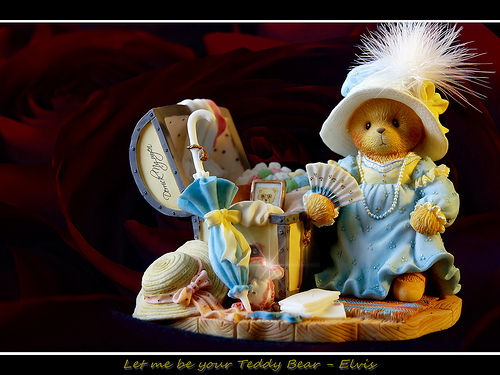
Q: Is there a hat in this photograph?
A: Yes, there is a hat.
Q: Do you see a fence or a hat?
A: Yes, there is a hat.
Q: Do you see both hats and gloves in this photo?
A: No, there is a hat but no gloves.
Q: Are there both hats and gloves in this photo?
A: No, there is a hat but no gloves.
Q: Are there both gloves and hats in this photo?
A: No, there is a hat but no gloves.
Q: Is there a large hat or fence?
A: Yes, there is a large hat.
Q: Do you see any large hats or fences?
A: Yes, there is a large hat.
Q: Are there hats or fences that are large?
A: Yes, the hat is large.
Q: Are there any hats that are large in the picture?
A: Yes, there is a large hat.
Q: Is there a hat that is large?
A: Yes, there is a hat that is large.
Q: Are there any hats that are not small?
A: Yes, there is a large hat.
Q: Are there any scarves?
A: No, there are no scarves.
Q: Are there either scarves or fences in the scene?
A: No, there are no scarves or fences.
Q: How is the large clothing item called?
A: The clothing item is a hat.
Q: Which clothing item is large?
A: The clothing item is a hat.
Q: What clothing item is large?
A: The clothing item is a hat.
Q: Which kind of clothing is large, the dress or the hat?
A: The hat is large.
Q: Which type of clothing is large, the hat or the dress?
A: The hat is large.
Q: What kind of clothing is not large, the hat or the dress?
A: The dress is not large.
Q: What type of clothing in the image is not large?
A: The clothing is a dress.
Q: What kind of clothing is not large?
A: The clothing is a dress.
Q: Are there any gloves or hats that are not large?
A: No, there is a hat but it is large.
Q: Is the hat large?
A: Yes, the hat is large.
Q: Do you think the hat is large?
A: Yes, the hat is large.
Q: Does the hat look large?
A: Yes, the hat is large.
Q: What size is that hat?
A: The hat is large.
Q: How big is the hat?
A: The hat is large.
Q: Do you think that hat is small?
A: No, the hat is large.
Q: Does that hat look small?
A: No, the hat is large.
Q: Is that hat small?
A: No, the hat is large.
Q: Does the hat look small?
A: No, the hat is large.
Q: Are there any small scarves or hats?
A: No, there is a hat but it is large.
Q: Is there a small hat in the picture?
A: No, there is a hat but it is large.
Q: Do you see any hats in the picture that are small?
A: No, there is a hat but it is large.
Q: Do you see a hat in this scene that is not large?
A: No, there is a hat but it is large.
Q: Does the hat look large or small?
A: The hat is large.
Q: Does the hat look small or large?
A: The hat is large.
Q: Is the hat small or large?
A: The hat is large.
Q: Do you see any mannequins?
A: No, there are no mannequins.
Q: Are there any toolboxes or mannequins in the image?
A: No, there are no mannequins or toolboxes.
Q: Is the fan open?
A: Yes, the fan is open.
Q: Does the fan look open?
A: Yes, the fan is open.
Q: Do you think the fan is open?
A: Yes, the fan is open.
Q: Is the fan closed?
A: No, the fan is open.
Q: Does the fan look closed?
A: No, the fan is open.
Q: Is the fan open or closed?
A: The fan is open.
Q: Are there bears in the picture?
A: Yes, there is a bear.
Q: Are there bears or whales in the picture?
A: Yes, there is a bear.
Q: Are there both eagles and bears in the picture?
A: No, there is a bear but no eagles.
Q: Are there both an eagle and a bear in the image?
A: No, there is a bear but no eagles.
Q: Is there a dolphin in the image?
A: No, there are no dolphins.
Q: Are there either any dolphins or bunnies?
A: No, there are no dolphins or bunnies.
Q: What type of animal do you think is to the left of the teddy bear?
A: The animal is a bear.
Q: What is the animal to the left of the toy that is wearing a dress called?
A: The animal is a bear.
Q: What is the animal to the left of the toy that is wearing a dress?
A: The animal is a bear.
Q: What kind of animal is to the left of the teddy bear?
A: The animal is a bear.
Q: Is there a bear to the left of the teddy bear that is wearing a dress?
A: Yes, there is a bear to the left of the teddy bear.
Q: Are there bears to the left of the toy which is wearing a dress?
A: Yes, there is a bear to the left of the teddy bear.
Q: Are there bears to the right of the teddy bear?
A: No, the bear is to the left of the teddy bear.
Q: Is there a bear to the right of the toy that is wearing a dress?
A: No, the bear is to the left of the teddy bear.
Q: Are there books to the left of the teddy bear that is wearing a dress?
A: No, there is a bear to the left of the teddy bear.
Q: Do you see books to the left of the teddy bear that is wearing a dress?
A: No, there is a bear to the left of the teddy bear.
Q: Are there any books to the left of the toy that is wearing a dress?
A: No, there is a bear to the left of the teddy bear.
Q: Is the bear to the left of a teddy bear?
A: Yes, the bear is to the left of a teddy bear.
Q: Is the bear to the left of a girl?
A: No, the bear is to the left of a teddy bear.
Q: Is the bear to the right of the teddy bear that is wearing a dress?
A: No, the bear is to the left of the teddy bear.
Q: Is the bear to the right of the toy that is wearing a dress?
A: No, the bear is to the left of the teddy bear.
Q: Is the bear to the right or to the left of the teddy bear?
A: The bear is to the left of the teddy bear.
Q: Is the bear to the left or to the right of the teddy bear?
A: The bear is to the left of the teddy bear.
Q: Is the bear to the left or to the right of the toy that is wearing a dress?
A: The bear is to the left of the teddy bear.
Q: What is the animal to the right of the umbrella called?
A: The animal is a bear.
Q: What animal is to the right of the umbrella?
A: The animal is a bear.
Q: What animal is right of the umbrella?
A: The animal is a bear.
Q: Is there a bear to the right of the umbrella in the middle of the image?
A: Yes, there is a bear to the right of the umbrella.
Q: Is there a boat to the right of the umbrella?
A: No, there is a bear to the right of the umbrella.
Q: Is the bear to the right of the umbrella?
A: Yes, the bear is to the right of the umbrella.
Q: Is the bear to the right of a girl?
A: No, the bear is to the right of the umbrella.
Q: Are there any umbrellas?
A: Yes, there is an umbrella.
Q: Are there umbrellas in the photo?
A: Yes, there is an umbrella.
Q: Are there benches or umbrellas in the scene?
A: Yes, there is an umbrella.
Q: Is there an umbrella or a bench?
A: Yes, there is an umbrella.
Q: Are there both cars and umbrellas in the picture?
A: No, there is an umbrella but no cars.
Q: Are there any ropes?
A: No, there are no ropes.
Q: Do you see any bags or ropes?
A: No, there are no ropes or bags.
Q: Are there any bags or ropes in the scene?
A: No, there are no ropes or bags.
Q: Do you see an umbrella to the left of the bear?
A: Yes, there is an umbrella to the left of the bear.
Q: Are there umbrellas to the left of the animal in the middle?
A: Yes, there is an umbrella to the left of the bear.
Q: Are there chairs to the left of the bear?
A: No, there is an umbrella to the left of the bear.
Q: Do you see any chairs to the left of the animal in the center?
A: No, there is an umbrella to the left of the bear.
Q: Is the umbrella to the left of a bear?
A: Yes, the umbrella is to the left of a bear.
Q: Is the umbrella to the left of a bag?
A: No, the umbrella is to the left of a bear.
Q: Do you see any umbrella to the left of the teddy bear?
A: Yes, there is an umbrella to the left of the teddy bear.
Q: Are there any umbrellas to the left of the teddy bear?
A: Yes, there is an umbrella to the left of the teddy bear.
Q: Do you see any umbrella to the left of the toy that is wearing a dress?
A: Yes, there is an umbrella to the left of the teddy bear.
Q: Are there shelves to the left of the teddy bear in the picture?
A: No, there is an umbrella to the left of the teddy bear.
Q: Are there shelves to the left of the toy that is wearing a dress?
A: No, there is an umbrella to the left of the teddy bear.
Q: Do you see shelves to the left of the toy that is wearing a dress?
A: No, there is an umbrella to the left of the teddy bear.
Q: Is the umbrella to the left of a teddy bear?
A: Yes, the umbrella is to the left of a teddy bear.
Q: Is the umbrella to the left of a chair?
A: No, the umbrella is to the left of a teddy bear.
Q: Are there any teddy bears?
A: Yes, there is a teddy bear.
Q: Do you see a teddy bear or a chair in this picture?
A: Yes, there is a teddy bear.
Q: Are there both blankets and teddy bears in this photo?
A: No, there is a teddy bear but no blankets.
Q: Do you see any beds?
A: No, there are no beds.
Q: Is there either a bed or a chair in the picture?
A: No, there are no beds or chairs.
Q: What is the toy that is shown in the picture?
A: The toy is a teddy bear.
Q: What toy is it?
A: The toy is a teddy bear.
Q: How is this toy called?
A: This is a teddy bear.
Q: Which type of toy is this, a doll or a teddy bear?
A: This is a teddy bear.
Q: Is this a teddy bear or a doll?
A: This is a teddy bear.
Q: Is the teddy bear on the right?
A: Yes, the teddy bear is on the right of the image.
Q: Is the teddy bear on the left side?
A: No, the teddy bear is on the right of the image.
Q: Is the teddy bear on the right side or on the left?
A: The teddy bear is on the right of the image.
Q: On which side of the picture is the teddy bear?
A: The teddy bear is on the right of the image.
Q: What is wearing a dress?
A: The teddy bear is wearing a dress.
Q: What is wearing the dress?
A: The teddy bear is wearing a dress.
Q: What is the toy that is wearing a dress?
A: The toy is a teddy bear.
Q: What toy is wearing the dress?
A: The toy is a teddy bear.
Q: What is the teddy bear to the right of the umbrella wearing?
A: The teddy bear is wearing a dress.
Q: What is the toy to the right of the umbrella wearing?
A: The teddy bear is wearing a dress.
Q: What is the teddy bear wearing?
A: The teddy bear is wearing a dress.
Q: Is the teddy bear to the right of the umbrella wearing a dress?
A: Yes, the teddy bear is wearing a dress.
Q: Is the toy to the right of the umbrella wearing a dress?
A: Yes, the teddy bear is wearing a dress.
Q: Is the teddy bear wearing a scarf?
A: No, the teddy bear is wearing a dress.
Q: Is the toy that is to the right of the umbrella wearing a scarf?
A: No, the teddy bear is wearing a dress.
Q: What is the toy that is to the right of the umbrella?
A: The toy is a teddy bear.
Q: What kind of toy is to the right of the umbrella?
A: The toy is a teddy bear.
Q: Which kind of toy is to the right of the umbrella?
A: The toy is a teddy bear.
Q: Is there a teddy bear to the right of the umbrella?
A: Yes, there is a teddy bear to the right of the umbrella.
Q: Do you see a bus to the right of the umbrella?
A: No, there is a teddy bear to the right of the umbrella.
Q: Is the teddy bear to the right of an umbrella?
A: Yes, the teddy bear is to the right of an umbrella.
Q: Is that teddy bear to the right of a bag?
A: No, the teddy bear is to the right of an umbrella.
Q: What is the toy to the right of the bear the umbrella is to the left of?
A: The toy is a teddy bear.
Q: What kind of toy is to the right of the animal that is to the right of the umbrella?
A: The toy is a teddy bear.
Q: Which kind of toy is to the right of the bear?
A: The toy is a teddy bear.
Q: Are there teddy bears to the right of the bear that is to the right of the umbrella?
A: Yes, there is a teddy bear to the right of the bear.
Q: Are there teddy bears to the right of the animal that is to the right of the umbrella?
A: Yes, there is a teddy bear to the right of the bear.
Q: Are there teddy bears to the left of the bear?
A: No, the teddy bear is to the right of the bear.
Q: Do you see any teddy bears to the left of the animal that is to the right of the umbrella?
A: No, the teddy bear is to the right of the bear.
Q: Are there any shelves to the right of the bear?
A: No, there is a teddy bear to the right of the bear.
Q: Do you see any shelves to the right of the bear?
A: No, there is a teddy bear to the right of the bear.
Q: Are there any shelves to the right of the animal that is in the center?
A: No, there is a teddy bear to the right of the bear.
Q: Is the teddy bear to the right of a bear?
A: Yes, the teddy bear is to the right of a bear.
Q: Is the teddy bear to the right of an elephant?
A: No, the teddy bear is to the right of a bear.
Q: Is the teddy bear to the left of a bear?
A: No, the teddy bear is to the right of a bear.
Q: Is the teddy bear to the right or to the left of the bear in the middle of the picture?
A: The teddy bear is to the right of the bear.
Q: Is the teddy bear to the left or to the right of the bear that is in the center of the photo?
A: The teddy bear is to the right of the bear.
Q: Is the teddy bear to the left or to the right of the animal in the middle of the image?
A: The teddy bear is to the right of the bear.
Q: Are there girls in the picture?
A: No, there are no girls.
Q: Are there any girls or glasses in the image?
A: No, there are no girls or glasses.